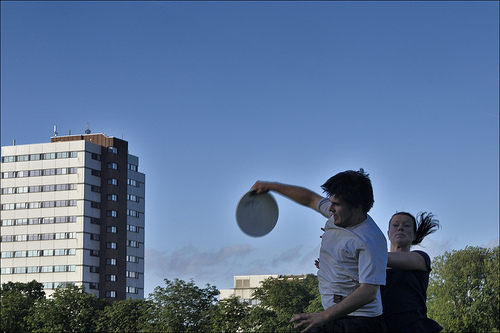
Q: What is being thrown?
A: Frisbee.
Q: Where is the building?
A: To the left of the people.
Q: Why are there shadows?
A: Sunshine.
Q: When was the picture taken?
A: Daytime.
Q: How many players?
A: Two.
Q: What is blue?
A: Sky.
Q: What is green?
A: Tree.